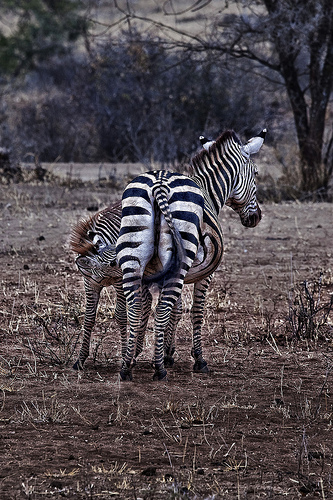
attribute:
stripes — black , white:
[171, 183, 207, 229]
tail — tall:
[131, 173, 189, 286]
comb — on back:
[178, 116, 238, 175]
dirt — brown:
[61, 400, 272, 482]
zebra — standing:
[58, 101, 306, 451]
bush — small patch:
[60, 451, 121, 495]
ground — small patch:
[80, 354, 267, 483]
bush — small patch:
[202, 425, 252, 472]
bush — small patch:
[226, 448, 324, 493]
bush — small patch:
[253, 385, 315, 427]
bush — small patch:
[280, 268, 319, 347]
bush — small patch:
[215, 310, 268, 369]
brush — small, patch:
[26, 275, 68, 346]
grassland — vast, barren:
[6, 179, 331, 498]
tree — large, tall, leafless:
[84, 3, 331, 202]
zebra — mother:
[115, 125, 273, 384]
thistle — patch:
[284, 270, 331, 346]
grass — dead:
[1, 326, 329, 499]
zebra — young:
[66, 191, 215, 373]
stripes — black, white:
[219, 144, 240, 175]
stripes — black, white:
[202, 155, 227, 204]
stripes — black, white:
[193, 161, 220, 214]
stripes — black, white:
[163, 170, 204, 193]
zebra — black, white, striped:
[77, 131, 262, 351]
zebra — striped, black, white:
[67, 127, 283, 337]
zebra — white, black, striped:
[74, 154, 252, 355]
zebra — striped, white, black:
[58, 151, 328, 462]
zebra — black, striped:
[70, 151, 244, 338]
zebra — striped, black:
[89, 158, 253, 317]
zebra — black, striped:
[80, 127, 275, 381]